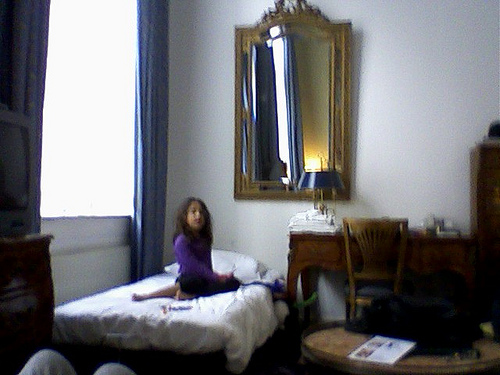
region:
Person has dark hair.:
[168, 195, 228, 265]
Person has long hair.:
[175, 173, 230, 268]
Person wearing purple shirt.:
[173, 247, 210, 281]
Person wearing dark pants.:
[173, 271, 244, 337]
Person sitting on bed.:
[138, 260, 224, 361]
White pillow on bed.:
[223, 259, 288, 342]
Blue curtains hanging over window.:
[110, 145, 192, 260]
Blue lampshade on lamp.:
[299, 162, 347, 223]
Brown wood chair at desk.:
[341, 215, 428, 327]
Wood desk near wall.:
[302, 202, 472, 285]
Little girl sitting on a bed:
[128, 185, 255, 312]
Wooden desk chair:
[339, 213, 413, 318]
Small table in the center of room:
[300, 300, 498, 373]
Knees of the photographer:
[11, 346, 140, 373]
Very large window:
[36, 0, 143, 223]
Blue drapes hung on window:
[130, 3, 165, 274]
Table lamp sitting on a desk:
[292, 155, 349, 232]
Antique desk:
[285, 222, 482, 352]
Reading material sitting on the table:
[347, 331, 421, 370]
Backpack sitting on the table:
[346, 270, 483, 356]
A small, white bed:
[53, 257, 278, 350]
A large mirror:
[236, 5, 351, 208]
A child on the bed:
[144, 185, 226, 309]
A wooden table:
[301, 317, 499, 372]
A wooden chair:
[334, 211, 414, 325]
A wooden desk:
[293, 225, 465, 310]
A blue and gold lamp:
[297, 152, 351, 227]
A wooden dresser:
[468, 144, 496, 324]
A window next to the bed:
[33, 1, 139, 205]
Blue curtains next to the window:
[0, 0, 167, 260]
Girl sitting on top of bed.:
[171, 192, 238, 247]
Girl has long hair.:
[176, 196, 234, 271]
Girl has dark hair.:
[166, 199, 283, 279]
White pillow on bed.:
[233, 242, 265, 292]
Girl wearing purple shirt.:
[163, 239, 227, 299]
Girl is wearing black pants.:
[188, 272, 233, 327]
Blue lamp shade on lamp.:
[292, 159, 335, 194]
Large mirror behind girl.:
[212, 120, 325, 202]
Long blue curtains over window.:
[120, 132, 208, 292]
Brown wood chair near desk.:
[333, 200, 440, 326]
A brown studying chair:
[336, 211, 408, 285]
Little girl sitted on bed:
[129, 194, 234, 309]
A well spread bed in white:
[56, 245, 279, 356]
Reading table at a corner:
[289, 190, 496, 281]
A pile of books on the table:
[287, 205, 339, 232]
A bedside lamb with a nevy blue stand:
[303, 147, 345, 199]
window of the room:
[53, 13, 130, 208]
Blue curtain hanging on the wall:
[124, 0, 172, 267]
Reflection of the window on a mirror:
[248, 30, 310, 186]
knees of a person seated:
[19, 346, 136, 373]